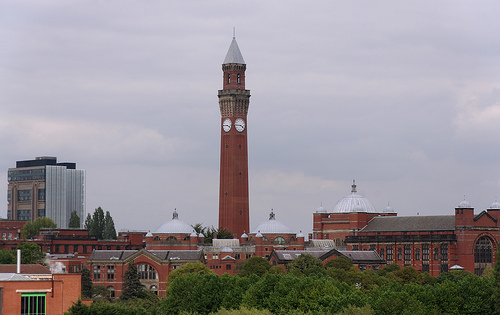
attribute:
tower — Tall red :
[208, 20, 266, 233]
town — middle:
[3, 137, 498, 314]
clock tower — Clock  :
[199, 38, 273, 227]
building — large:
[4, 155, 85, 240]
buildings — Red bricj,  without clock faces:
[12, 234, 496, 301]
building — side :
[15, 150, 116, 225]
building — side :
[81, 249, 165, 293]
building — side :
[4, 151, 89, 231]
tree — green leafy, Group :
[118, 256, 146, 301]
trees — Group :
[63, 242, 498, 312]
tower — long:
[204, 10, 271, 270]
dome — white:
[329, 180, 376, 215]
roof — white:
[133, 205, 201, 249]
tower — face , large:
[201, 24, 265, 234]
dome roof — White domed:
[333, 190, 373, 215]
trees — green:
[5, 205, 233, 312]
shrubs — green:
[161, 251, 498, 313]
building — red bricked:
[12, 19, 499, 294]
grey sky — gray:
[1, 0, 499, 240]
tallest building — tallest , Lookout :
[192, 27, 284, 226]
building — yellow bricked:
[1, 161, 91, 236]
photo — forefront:
[4, 6, 479, 308]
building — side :
[467, 230, 484, 270]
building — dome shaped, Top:
[303, 172, 397, 245]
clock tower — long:
[216, 28, 254, 242]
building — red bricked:
[313, 174, 398, 261]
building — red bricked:
[251, 205, 301, 247]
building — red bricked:
[216, 21, 253, 244]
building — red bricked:
[143, 202, 200, 256]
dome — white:
[248, 207, 298, 237]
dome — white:
[151, 202, 195, 232]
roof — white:
[328, 172, 381, 215]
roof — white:
[148, 201, 199, 234]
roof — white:
[248, 204, 305, 237]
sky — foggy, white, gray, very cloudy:
[0, 0, 500, 234]